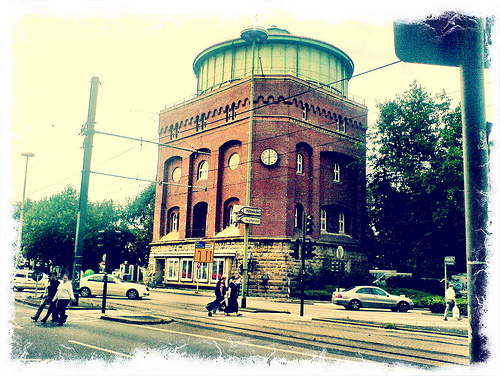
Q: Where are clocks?
A: On a building.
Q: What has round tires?
A: A car.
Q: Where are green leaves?
A: On trees.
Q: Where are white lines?
A: On the street.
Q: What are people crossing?
A: The street.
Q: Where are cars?
A: On the road.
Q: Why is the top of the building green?
A: Age.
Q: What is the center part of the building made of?
A: Brick.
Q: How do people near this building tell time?
A: By its clock.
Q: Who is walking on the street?
A: A lady and man.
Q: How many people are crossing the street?
A: 4.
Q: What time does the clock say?
A: 6pm.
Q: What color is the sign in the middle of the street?
A: Yellow.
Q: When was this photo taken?
A: Daytime.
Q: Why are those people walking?
A: To get across the street.